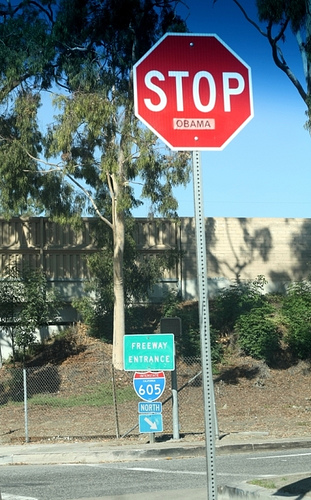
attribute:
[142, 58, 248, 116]
letter — white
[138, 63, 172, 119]
letter — white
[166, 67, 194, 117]
letter — white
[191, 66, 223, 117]
letter — white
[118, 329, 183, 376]
sign — green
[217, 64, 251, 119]
letter — white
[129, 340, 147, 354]
letter — white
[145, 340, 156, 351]
letter — white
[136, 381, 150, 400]
letter — white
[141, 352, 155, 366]
letter — white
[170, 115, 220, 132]
sticker — Obama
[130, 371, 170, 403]
sign — North 65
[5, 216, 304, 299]
wall — yellow, brick, light colored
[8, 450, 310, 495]
road — concrete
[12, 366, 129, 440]
fence — chain-link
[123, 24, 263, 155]
sign — octagon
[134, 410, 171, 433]
sign — direction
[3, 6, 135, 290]
trees — tall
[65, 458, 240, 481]
lines — white